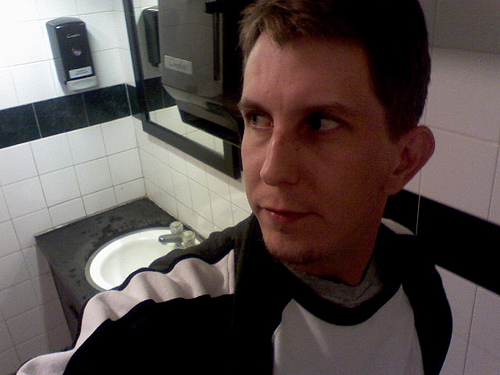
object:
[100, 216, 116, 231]
water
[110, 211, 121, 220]
splashes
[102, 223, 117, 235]
splashes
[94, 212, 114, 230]
water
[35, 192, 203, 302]
counter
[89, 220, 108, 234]
water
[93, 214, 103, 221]
splashes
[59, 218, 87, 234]
water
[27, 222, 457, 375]
top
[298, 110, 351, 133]
eye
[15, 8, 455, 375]
man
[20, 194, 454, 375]
shirt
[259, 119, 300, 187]
nose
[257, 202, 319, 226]
mouth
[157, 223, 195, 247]
faucet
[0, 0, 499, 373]
bathroom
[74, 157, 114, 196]
tile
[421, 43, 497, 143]
tile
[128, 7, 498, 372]
wall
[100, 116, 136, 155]
tile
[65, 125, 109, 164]
tile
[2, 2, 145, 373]
wall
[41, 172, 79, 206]
tile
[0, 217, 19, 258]
tile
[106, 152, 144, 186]
tile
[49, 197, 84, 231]
tile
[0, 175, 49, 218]
tile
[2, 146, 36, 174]
tile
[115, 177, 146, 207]
tile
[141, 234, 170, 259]
water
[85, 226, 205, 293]
sink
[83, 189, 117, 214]
tile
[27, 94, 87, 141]
tile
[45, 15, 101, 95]
soap dispenser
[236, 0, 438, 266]
head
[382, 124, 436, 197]
ear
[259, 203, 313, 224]
lips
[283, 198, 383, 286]
neck